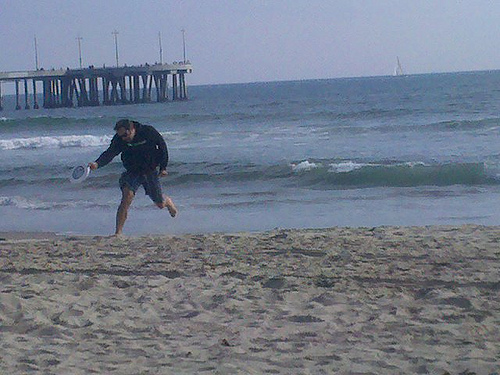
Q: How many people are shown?
A: 1.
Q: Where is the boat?
A: In the ocean.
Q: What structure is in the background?
A: Pier.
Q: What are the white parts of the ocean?
A: Waves.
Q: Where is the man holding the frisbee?
A: Right hand.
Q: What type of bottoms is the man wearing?
A: Shorts.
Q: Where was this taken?
A: Beach.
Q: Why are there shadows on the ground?
A: Sunny.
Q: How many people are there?
A: 1.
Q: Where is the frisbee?
A: In the man's right hand.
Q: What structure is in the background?
A: Pier.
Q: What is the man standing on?
A: Sand.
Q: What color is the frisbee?
A: White.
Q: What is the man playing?
A: Frisbee.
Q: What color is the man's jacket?
A: Black.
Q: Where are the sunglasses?
A: On the man's face.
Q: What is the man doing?
A: Playing frisbee.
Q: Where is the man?
A: Beach.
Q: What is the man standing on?
A: Sand.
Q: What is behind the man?
A: Ocean.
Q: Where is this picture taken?
A: The beach.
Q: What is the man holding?
A: A frisbee.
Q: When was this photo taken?
A: Daytime.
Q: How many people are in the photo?
A: One.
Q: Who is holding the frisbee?
A: The man.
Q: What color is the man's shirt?
A: Black.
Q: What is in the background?
A: The ocean.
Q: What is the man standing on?
A: The beach.